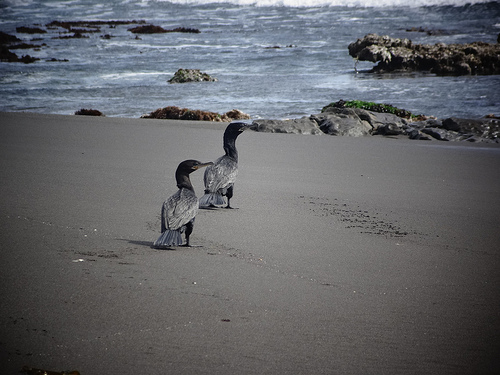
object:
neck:
[175, 173, 192, 190]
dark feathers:
[160, 196, 195, 233]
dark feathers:
[154, 232, 181, 247]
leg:
[222, 187, 234, 208]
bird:
[194, 115, 253, 210]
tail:
[149, 229, 187, 251]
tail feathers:
[152, 228, 184, 253]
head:
[174, 158, 211, 183]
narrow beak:
[195, 160, 212, 169]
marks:
[296, 192, 406, 239]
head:
[226, 118, 246, 139]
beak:
[248, 123, 260, 128]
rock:
[248, 101, 500, 144]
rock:
[352, 33, 499, 73]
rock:
[168, 68, 217, 83]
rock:
[136, 105, 248, 117]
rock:
[0, 32, 47, 48]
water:
[2, 4, 499, 127]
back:
[155, 190, 200, 247]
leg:
[183, 227, 192, 248]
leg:
[173, 228, 180, 245]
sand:
[3, 111, 499, 373]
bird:
[150, 158, 217, 248]